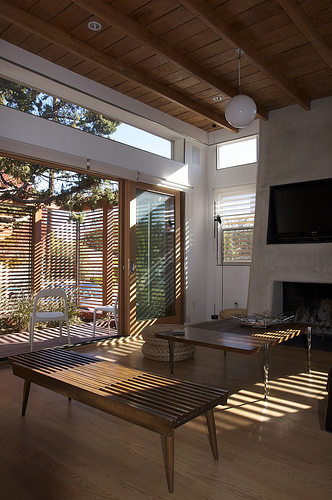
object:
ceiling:
[61, 14, 323, 131]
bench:
[18, 349, 218, 456]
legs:
[150, 433, 232, 482]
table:
[153, 315, 322, 377]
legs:
[170, 345, 291, 385]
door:
[121, 189, 189, 325]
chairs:
[27, 287, 122, 353]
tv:
[259, 174, 331, 254]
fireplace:
[270, 266, 330, 319]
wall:
[166, 145, 332, 312]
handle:
[126, 255, 138, 274]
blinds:
[227, 193, 263, 249]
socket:
[229, 297, 241, 318]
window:
[7, 85, 207, 166]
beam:
[41, 32, 267, 90]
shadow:
[174, 366, 309, 417]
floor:
[60, 350, 319, 481]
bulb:
[230, 101, 244, 127]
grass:
[13, 302, 92, 325]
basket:
[209, 301, 258, 323]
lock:
[123, 261, 141, 287]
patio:
[10, 197, 125, 354]